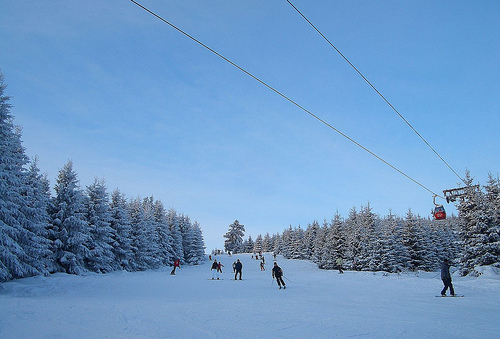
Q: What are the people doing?
A: Skiing.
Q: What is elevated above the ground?
A: A cable car.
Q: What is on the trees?
A: Snow.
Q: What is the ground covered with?
A: Snow.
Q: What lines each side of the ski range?
A: Tress.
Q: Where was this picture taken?
A: On the snowy mountain.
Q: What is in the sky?
A: The sky is blue and there are no clouds.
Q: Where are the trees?
A: The trees are on the side of the slope.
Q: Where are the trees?
A: The trees are behind the skiers.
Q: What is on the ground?
A: Snow.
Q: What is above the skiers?
A: Blue skies.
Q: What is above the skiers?
A: Ski lift cables.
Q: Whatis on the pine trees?
A: Snow.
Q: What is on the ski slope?
A: Snow.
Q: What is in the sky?
A: White clouds.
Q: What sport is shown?
A: Skiing.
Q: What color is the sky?
A: Blue.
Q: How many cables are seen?
A: Two.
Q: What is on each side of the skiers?
A: Trees.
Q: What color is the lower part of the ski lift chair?
A: Orange.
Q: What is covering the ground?
A: Snow.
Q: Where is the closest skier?
A: At the lower right.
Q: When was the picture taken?
A: Day time.